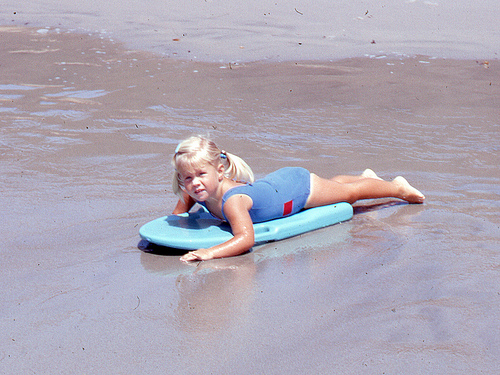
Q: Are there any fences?
A: No, there are no fences.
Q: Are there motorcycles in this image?
A: No, there are no motorcycles.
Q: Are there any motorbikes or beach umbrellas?
A: No, there are no motorbikes or beach umbrellas.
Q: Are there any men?
A: No, there are no men.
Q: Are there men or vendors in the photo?
A: No, there are no men or vendors.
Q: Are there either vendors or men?
A: No, there are no men or vendors.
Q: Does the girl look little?
A: Yes, the girl is little.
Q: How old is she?
A: The girl is little.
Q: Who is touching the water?
A: The girl is touching the water.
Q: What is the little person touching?
A: The girl is touching the water.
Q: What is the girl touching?
A: The girl is touching the water.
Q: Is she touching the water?
A: Yes, the girl is touching the water.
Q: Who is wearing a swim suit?
A: The girl is wearing a swim suit.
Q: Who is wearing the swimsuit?
A: The girl is wearing a swim suit.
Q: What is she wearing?
A: The girl is wearing a swimsuit.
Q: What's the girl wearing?
A: The girl is wearing a swimsuit.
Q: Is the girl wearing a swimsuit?
A: Yes, the girl is wearing a swimsuit.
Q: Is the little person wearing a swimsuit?
A: Yes, the girl is wearing a swimsuit.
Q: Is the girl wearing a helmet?
A: No, the girl is wearing a swimsuit.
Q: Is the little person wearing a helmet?
A: No, the girl is wearing a swimsuit.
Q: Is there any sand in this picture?
A: Yes, there is sand.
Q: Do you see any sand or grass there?
A: Yes, there is sand.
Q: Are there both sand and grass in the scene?
A: No, there is sand but no grass.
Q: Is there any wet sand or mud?
A: Yes, there is wet sand.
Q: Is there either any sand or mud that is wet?
A: Yes, the sand is wet.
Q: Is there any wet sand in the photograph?
A: Yes, there is wet sand.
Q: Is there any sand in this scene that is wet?
A: Yes, there is sand that is wet.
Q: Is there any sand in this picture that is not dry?
A: Yes, there is wet sand.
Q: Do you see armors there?
A: No, there are no armors.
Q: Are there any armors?
A: No, there are no armors.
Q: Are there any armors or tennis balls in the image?
A: No, there are no armors or tennis balls.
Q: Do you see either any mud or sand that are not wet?
A: No, there is sand but it is wet.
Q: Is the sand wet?
A: Yes, the sand is wet.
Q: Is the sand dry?
A: No, the sand is wet.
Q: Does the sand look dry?
A: No, the sand is wet.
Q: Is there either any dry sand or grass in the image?
A: No, there is sand but it is wet.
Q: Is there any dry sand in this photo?
A: No, there is sand but it is wet.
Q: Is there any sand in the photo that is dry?
A: No, there is sand but it is wet.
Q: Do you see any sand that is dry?
A: No, there is sand but it is wet.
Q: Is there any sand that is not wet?
A: No, there is sand but it is wet.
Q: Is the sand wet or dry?
A: The sand is wet.